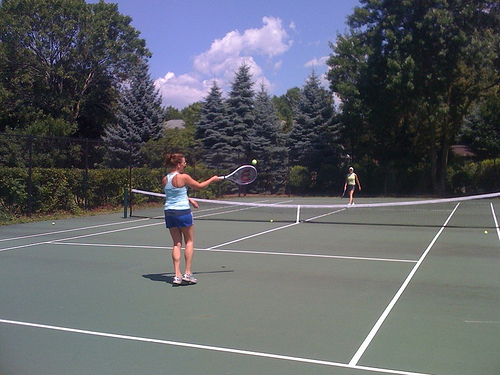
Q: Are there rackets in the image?
A: Yes, there is a racket.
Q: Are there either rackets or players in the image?
A: Yes, there is a racket.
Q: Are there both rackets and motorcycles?
A: No, there is a racket but no motorcycles.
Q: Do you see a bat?
A: No, there are no bats.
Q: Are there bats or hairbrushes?
A: No, there are no bats or hairbrushes.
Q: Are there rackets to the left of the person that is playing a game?
A: Yes, there is a racket to the left of the person.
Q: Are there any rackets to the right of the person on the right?
A: No, the racket is to the left of the person.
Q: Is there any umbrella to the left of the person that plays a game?
A: No, there is a racket to the left of the person.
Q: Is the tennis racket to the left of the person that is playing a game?
A: Yes, the tennis racket is to the left of the person.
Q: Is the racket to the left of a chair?
A: No, the racket is to the left of the person.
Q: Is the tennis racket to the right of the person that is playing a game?
A: No, the tennis racket is to the left of the person.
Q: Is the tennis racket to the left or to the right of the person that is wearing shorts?
A: The tennis racket is to the left of the person.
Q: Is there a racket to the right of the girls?
A: Yes, there is a racket to the right of the girls.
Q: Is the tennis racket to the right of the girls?
A: Yes, the tennis racket is to the right of the girls.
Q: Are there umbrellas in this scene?
A: No, there are no umbrellas.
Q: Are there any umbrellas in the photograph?
A: No, there are no umbrellas.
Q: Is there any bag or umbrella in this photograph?
A: No, there are no umbrellas or bags.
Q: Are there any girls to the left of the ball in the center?
A: Yes, there are girls to the left of the ball.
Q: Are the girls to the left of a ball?
A: Yes, the girls are to the left of a ball.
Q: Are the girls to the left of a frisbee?
A: No, the girls are to the left of a ball.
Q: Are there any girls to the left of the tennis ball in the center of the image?
A: Yes, there are girls to the left of the tennis ball.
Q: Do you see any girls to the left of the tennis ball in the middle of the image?
A: Yes, there are girls to the left of the tennis ball.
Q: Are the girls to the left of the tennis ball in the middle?
A: Yes, the girls are to the left of the tennis ball.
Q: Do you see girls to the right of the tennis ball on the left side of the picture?
A: Yes, there are girls to the right of the tennis ball.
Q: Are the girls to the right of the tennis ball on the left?
A: Yes, the girls are to the right of the tennis ball.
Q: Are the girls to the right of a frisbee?
A: No, the girls are to the right of the tennis ball.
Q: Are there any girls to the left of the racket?
A: Yes, there are girls to the left of the racket.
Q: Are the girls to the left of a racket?
A: Yes, the girls are to the left of a racket.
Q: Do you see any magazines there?
A: No, there are no magazines.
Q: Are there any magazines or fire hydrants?
A: No, there are no magazines or fire hydrants.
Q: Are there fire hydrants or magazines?
A: No, there are no magazines or fire hydrants.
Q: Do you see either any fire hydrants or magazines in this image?
A: No, there are no magazines or fire hydrants.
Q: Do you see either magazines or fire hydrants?
A: No, there are no magazines or fire hydrants.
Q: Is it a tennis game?
A: Yes, this is a tennis game.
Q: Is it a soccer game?
A: No, this is a tennis game.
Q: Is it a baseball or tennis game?
A: This is a tennis game.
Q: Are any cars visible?
A: No, there are no cars.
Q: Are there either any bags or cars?
A: No, there are no cars or bags.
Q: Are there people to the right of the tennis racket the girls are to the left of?
A: Yes, there is a person to the right of the tennis racket.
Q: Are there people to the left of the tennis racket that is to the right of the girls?
A: No, the person is to the right of the racket.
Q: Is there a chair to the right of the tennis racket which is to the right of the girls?
A: No, there is a person to the right of the tennis racket.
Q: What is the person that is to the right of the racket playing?
A: The person is playing a game.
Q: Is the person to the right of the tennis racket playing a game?
A: Yes, the person is playing a game.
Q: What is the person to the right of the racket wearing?
A: The person is wearing shorts.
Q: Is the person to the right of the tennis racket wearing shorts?
A: Yes, the person is wearing shorts.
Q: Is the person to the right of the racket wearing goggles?
A: No, the person is wearing shorts.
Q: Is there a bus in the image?
A: No, there are no buses.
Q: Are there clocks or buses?
A: No, there are no buses or clocks.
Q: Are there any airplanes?
A: No, there are no airplanes.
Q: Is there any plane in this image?
A: No, there are no airplanes.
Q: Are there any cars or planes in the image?
A: No, there are no planes or cars.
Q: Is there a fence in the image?
A: Yes, there is a fence.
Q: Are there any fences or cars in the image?
A: Yes, there is a fence.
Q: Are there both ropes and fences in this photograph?
A: No, there is a fence but no ropes.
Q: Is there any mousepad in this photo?
A: No, there are no mouse pads.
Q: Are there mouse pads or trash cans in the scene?
A: No, there are no mouse pads or trash cans.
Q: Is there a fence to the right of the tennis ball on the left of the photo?
A: Yes, there is a fence to the right of the tennis ball.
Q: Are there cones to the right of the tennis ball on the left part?
A: No, there is a fence to the right of the tennis ball.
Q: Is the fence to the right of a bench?
A: No, the fence is to the right of a tennis ball.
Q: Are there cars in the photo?
A: No, there are no cars.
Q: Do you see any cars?
A: No, there are no cars.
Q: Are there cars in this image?
A: No, there are no cars.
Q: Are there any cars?
A: No, there are no cars.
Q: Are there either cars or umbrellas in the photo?
A: No, there are no cars or umbrellas.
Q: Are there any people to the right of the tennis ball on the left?
A: Yes, there are people to the right of the tennis ball.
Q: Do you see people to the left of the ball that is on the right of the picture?
A: Yes, there are people to the left of the ball.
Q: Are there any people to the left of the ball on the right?
A: Yes, there are people to the left of the ball.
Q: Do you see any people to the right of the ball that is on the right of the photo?
A: No, the people are to the left of the ball.